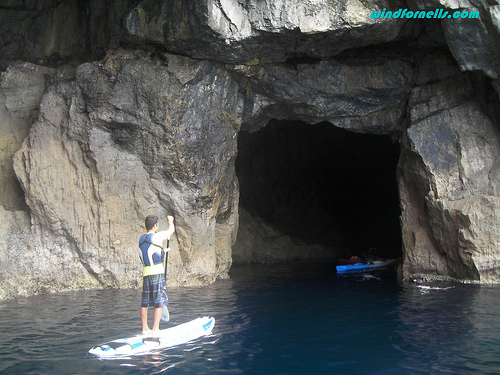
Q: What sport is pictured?
A: Paddleboarding.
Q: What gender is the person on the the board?
A: Male.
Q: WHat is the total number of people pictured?
A: 1.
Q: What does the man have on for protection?
A: Life vest.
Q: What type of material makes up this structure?
A: Stone.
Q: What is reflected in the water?
A: Stones.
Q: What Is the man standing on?
A: A kayak.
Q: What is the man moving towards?
A: A cave.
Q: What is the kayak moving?
A: A pool of water.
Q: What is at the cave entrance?
A: A large rock.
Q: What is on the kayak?
A: A man.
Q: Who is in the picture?
A: A man.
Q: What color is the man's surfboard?
A: White.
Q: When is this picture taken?
A: Dayrime.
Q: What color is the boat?
A: Blue.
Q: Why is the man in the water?
A: Going to cave.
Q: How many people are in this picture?
A: One.